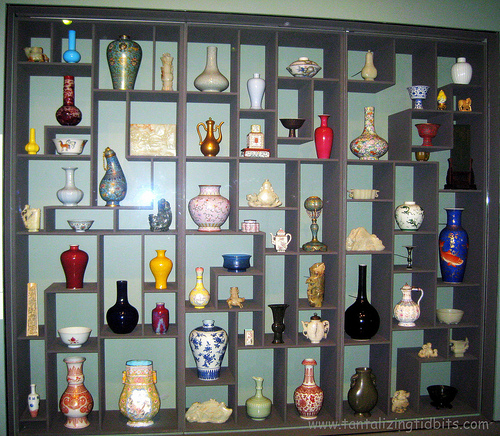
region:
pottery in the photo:
[175, 191, 387, 351]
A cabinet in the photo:
[135, 99, 380, 346]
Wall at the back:
[141, 185, 250, 242]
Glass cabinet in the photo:
[182, 22, 389, 294]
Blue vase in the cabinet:
[445, 206, 469, 286]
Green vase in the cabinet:
[233, 366, 279, 431]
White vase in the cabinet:
[196, 38, 226, 93]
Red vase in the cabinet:
[312, 114, 336, 164]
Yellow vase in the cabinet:
[24, 127, 43, 163]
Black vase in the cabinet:
[106, 272, 142, 338]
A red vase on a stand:
[293, 358, 325, 419]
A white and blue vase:
[189, 318, 226, 380]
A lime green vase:
[245, 373, 273, 420]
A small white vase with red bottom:
[26, 382, 41, 417]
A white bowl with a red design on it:
[58, 325, 91, 347]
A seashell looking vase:
[185, 398, 232, 422]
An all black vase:
[104, 279, 139, 334]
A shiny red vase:
[59, 242, 90, 289]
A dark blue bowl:
[222, 252, 252, 272]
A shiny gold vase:
[197, 118, 225, 156]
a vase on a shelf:
[187, 178, 232, 232]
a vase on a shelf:
[59, 355, 92, 429]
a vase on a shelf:
[113, 355, 159, 430]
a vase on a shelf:
[244, 372, 271, 420]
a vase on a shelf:
[293, 353, 323, 419]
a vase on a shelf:
[346, 363, 378, 417]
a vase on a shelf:
[56, 236, 93, 289]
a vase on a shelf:
[106, 276, 141, 335]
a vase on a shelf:
[148, 245, 175, 288]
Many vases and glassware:
[18, 12, 490, 417]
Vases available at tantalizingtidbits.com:
[298, 395, 496, 435]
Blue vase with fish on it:
[436, 207, 476, 280]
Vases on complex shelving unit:
[15, 12, 489, 422]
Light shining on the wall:
[121, 170, 180, 223]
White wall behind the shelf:
[27, 22, 475, 405]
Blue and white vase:
[192, 320, 232, 383]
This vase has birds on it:
[184, 312, 231, 381]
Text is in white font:
[303, 412, 498, 432]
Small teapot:
[297, 313, 337, 344]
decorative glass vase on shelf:
[104, 33, 144, 90]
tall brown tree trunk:
[27, 381, 39, 416]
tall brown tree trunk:
[58, 355, 92, 428]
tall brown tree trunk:
[114, 357, 161, 428]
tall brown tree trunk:
[189, 320, 228, 379]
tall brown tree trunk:
[248, 372, 270, 421]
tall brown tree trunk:
[296, 356, 323, 418]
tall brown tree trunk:
[268, 300, 287, 340]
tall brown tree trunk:
[150, 298, 172, 331]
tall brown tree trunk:
[59, 242, 88, 287]